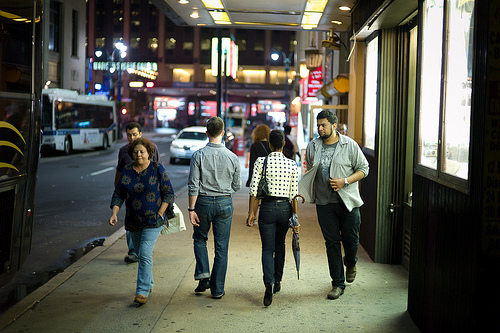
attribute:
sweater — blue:
[110, 165, 168, 230]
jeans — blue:
[188, 194, 248, 266]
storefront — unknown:
[349, 3, 498, 330]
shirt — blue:
[115, 159, 171, 216]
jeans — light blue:
[128, 228, 162, 297]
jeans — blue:
[171, 175, 242, 305]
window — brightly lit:
[411, 0, 476, 195]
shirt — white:
[246, 148, 303, 201]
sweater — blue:
[127, 177, 158, 222]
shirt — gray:
[185, 143, 245, 196]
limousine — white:
[167, 125, 211, 165]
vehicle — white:
[168, 125, 226, 165]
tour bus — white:
[40, 86, 120, 154]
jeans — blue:
[190, 186, 240, 311]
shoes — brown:
[109, 277, 166, 316]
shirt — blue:
[187, 135, 242, 204]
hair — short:
[125, 136, 153, 163]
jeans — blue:
[125, 221, 164, 298]